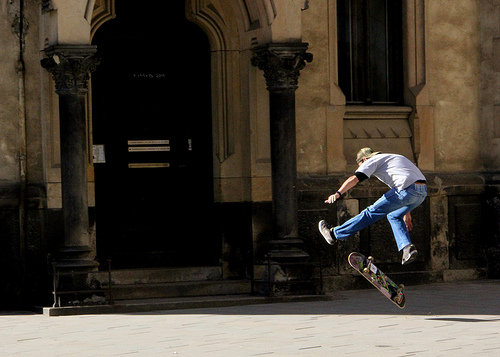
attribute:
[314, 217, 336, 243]
sneaker — black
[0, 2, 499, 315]
building — big, huge, beige, black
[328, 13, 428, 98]
window — dark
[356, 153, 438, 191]
shirt — grey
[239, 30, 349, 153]
pillar — black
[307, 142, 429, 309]
man — midair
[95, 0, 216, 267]
door — big, black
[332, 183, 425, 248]
jeans — blue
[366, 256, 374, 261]
wheel — yellow